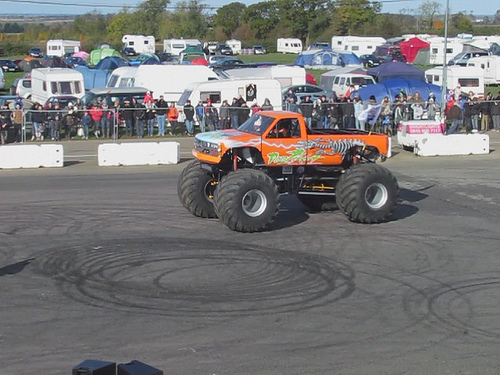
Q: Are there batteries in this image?
A: No, there are no batteries.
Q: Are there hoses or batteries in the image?
A: No, there are no batteries or hoses.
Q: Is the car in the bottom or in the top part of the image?
A: The car is in the top of the image.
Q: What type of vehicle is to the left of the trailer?
A: The vehicle is a car.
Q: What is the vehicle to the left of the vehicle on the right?
A: The vehicle is a car.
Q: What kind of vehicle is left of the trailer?
A: The vehicle is a car.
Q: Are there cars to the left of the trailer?
A: Yes, there is a car to the left of the trailer.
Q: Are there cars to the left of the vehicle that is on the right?
A: Yes, there is a car to the left of the trailer.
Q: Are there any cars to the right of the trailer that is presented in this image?
A: No, the car is to the left of the trailer.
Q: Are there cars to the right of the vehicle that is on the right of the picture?
A: No, the car is to the left of the trailer.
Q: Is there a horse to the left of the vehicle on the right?
A: No, there is a car to the left of the trailer.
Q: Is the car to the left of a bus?
A: No, the car is to the left of the trailer.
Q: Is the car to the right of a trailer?
A: No, the car is to the left of a trailer.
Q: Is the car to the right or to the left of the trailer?
A: The car is to the left of the trailer.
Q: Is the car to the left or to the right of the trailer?
A: The car is to the left of the trailer.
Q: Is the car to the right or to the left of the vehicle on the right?
A: The car is to the left of the trailer.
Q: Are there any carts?
A: No, there are no carts.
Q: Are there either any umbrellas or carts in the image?
A: No, there are no carts or umbrellas.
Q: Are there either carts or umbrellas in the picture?
A: No, there are no carts or umbrellas.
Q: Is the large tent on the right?
A: Yes, the tent is on the right of the image.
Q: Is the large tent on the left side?
A: No, the tent is on the right of the image.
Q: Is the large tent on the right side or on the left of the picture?
A: The tent is on the right of the image.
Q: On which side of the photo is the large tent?
A: The tent is on the right of the image.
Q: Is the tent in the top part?
A: Yes, the tent is in the top of the image.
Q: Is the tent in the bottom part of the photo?
A: No, the tent is in the top of the image.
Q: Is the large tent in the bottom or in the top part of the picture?
A: The tent is in the top of the image.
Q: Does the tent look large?
A: Yes, the tent is large.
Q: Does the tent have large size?
A: Yes, the tent is large.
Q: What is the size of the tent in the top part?
A: The tent is large.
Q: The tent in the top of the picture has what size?
A: The tent is large.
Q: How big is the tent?
A: The tent is large.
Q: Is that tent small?
A: No, the tent is large.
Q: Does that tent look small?
A: No, the tent is large.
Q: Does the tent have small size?
A: No, the tent is large.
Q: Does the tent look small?
A: No, the tent is large.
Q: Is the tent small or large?
A: The tent is large.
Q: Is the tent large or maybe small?
A: The tent is large.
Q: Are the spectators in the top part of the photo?
A: Yes, the spectators are in the top of the image.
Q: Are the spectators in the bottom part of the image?
A: No, the spectators are in the top of the image.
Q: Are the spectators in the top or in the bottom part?
A: The spectators are in the top of the image.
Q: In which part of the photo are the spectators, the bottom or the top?
A: The spectators are in the top of the image.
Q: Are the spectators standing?
A: Yes, the spectators are standing.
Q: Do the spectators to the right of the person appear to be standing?
A: Yes, the spectators are standing.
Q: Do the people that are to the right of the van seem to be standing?
A: Yes, the spectators are standing.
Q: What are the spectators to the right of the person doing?
A: The spectators are standing.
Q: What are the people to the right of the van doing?
A: The spectators are standing.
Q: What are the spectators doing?
A: The spectators are standing.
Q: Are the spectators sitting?
A: No, the spectators are standing.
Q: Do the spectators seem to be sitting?
A: No, the spectators are standing.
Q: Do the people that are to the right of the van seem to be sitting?
A: No, the spectators are standing.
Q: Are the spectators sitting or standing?
A: The spectators are standing.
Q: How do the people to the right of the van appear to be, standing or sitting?
A: The spectators are standing.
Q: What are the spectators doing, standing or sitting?
A: The spectators are standing.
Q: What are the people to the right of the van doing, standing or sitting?
A: The spectators are standing.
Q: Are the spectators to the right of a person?
A: Yes, the spectators are to the right of a person.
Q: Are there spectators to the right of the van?
A: Yes, there are spectators to the right of the van.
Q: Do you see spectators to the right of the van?
A: Yes, there are spectators to the right of the van.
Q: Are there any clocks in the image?
A: No, there are no clocks.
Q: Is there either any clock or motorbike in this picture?
A: No, there are no clocks or motorcycles.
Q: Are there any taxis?
A: Yes, there is a taxi.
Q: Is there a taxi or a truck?
A: Yes, there is a taxi.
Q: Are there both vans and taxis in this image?
A: Yes, there are both a taxi and a van.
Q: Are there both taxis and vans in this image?
A: Yes, there are both a taxi and a van.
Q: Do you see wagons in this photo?
A: No, there are no wagons.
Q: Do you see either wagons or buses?
A: No, there are no wagons or buses.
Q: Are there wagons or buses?
A: No, there are no wagons or buses.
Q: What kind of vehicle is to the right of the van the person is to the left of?
A: The vehicle is a taxi.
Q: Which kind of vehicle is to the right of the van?
A: The vehicle is a taxi.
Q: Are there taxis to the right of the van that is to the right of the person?
A: Yes, there is a taxi to the right of the van.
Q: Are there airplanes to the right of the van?
A: No, there is a taxi to the right of the van.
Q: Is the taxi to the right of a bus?
A: No, the taxi is to the right of the van.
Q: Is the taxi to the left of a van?
A: No, the taxi is to the right of a van.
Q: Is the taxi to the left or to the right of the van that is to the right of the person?
A: The taxi is to the right of the van.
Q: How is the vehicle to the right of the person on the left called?
A: The vehicle is a taxi.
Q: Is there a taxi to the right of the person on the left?
A: Yes, there is a taxi to the right of the person.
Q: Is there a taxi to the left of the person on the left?
A: No, the taxi is to the right of the person.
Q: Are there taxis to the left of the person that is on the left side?
A: No, the taxi is to the right of the person.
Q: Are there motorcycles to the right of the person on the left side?
A: No, there is a taxi to the right of the person.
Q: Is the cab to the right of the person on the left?
A: Yes, the cab is to the right of the person.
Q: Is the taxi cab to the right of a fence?
A: No, the taxi cab is to the right of the person.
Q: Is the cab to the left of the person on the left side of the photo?
A: No, the cab is to the right of the person.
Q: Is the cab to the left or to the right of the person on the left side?
A: The cab is to the right of the person.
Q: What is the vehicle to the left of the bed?
A: The vehicle is a taxi.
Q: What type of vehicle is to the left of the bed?
A: The vehicle is a taxi.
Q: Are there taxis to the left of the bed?
A: Yes, there is a taxi to the left of the bed.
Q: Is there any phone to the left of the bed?
A: No, there is a taxi to the left of the bed.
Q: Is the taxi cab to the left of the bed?
A: Yes, the taxi cab is to the left of the bed.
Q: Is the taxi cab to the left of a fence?
A: No, the taxi cab is to the left of the bed.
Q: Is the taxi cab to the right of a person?
A: Yes, the taxi cab is to the right of a person.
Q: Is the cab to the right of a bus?
A: No, the cab is to the right of a person.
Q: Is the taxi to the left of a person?
A: No, the taxi is to the right of a person.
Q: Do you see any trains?
A: No, there are no trains.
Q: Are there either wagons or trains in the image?
A: No, there are no trains or wagons.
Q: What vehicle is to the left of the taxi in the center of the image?
A: The vehicle is a van.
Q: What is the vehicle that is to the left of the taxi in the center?
A: The vehicle is a van.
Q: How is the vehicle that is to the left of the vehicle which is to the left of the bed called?
A: The vehicle is a van.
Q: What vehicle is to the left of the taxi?
A: The vehicle is a van.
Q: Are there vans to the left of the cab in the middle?
A: Yes, there is a van to the left of the cab.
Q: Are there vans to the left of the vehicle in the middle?
A: Yes, there is a van to the left of the cab.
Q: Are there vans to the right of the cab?
A: No, the van is to the left of the cab.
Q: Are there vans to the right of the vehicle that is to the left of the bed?
A: No, the van is to the left of the cab.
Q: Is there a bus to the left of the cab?
A: No, there is a van to the left of the cab.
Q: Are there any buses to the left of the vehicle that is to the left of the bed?
A: No, there is a van to the left of the cab.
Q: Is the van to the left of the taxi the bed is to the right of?
A: Yes, the van is to the left of the cab.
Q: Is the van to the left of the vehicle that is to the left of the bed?
A: Yes, the van is to the left of the cab.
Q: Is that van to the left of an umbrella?
A: No, the van is to the left of the cab.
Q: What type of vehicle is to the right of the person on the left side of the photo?
A: The vehicle is a van.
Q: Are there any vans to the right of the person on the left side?
A: Yes, there is a van to the right of the person.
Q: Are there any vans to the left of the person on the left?
A: No, the van is to the right of the person.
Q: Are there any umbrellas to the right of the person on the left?
A: No, there is a van to the right of the person.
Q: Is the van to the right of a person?
A: Yes, the van is to the right of a person.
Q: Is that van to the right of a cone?
A: No, the van is to the right of a person.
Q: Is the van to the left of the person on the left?
A: No, the van is to the right of the person.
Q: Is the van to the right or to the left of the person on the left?
A: The van is to the right of the person.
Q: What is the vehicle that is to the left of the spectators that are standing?
A: The vehicle is a van.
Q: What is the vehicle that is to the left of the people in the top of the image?
A: The vehicle is a van.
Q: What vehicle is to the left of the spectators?
A: The vehicle is a van.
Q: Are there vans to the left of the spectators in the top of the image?
A: Yes, there is a van to the left of the spectators.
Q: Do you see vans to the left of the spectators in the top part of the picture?
A: Yes, there is a van to the left of the spectators.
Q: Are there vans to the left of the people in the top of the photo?
A: Yes, there is a van to the left of the spectators.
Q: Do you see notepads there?
A: No, there are no notepads.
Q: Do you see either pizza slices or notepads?
A: No, there are no notepads or pizza slices.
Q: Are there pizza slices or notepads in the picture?
A: No, there are no notepads or pizza slices.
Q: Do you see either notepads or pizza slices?
A: No, there are no notepads or pizza slices.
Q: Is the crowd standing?
A: Yes, the crowd is standing.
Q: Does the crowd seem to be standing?
A: Yes, the crowd is standing.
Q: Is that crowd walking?
A: No, the crowd is standing.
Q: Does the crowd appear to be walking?
A: No, the crowd is standing.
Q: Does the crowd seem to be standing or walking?
A: The crowd is standing.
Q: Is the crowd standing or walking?
A: The crowd is standing.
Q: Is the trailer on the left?
A: No, the trailer is on the right of the image.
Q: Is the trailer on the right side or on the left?
A: The trailer is on the right of the image.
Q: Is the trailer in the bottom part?
A: No, the trailer is in the top of the image.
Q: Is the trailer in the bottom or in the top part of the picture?
A: The trailer is in the top of the image.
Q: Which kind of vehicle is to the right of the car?
A: The vehicle is a trailer.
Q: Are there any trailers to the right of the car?
A: Yes, there is a trailer to the right of the car.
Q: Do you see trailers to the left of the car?
A: No, the trailer is to the right of the car.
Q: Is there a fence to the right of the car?
A: No, there is a trailer to the right of the car.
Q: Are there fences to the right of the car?
A: No, there is a trailer to the right of the car.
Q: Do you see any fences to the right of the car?
A: No, there is a trailer to the right of the car.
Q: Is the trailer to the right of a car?
A: Yes, the trailer is to the right of a car.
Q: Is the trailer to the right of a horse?
A: No, the trailer is to the right of a car.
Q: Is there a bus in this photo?
A: No, there are no buses.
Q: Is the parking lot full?
A: Yes, the parking lot is full.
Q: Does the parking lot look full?
A: Yes, the parking lot is full.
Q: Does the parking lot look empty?
A: No, the parking lot is full.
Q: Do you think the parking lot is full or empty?
A: The parking lot is full.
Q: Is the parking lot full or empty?
A: The parking lot is full.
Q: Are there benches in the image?
A: No, there are no benches.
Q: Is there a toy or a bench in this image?
A: No, there are no benches or toys.